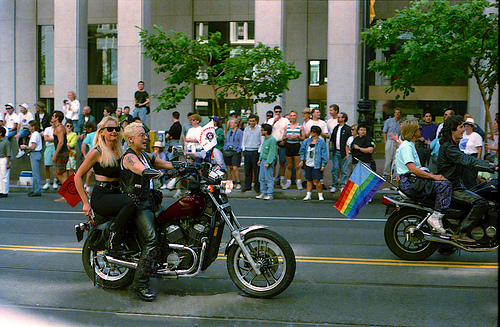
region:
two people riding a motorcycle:
[71, 116, 298, 308]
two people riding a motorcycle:
[369, 116, 499, 261]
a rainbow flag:
[326, 151, 400, 226]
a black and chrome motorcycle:
[71, 159, 297, 297]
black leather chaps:
[126, 192, 165, 291]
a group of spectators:
[213, 103, 346, 205]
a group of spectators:
[0, 96, 80, 194]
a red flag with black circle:
[51, 166, 87, 213]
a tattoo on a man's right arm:
[121, 150, 139, 170]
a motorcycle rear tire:
[379, 202, 437, 264]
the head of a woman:
[92, 115, 122, 145]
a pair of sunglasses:
[101, 124, 122, 134]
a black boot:
[128, 247, 158, 304]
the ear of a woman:
[97, 126, 105, 137]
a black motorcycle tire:
[224, 225, 297, 299]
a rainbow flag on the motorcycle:
[327, 155, 385, 221]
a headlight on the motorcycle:
[218, 177, 238, 195]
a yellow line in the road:
[1, 239, 498, 275]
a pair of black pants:
[88, 182, 138, 234]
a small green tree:
[126, 15, 303, 112]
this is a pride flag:
[321, 137, 404, 229]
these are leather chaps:
[130, 187, 169, 325]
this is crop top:
[93, 145, 123, 176]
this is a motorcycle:
[49, 167, 321, 314]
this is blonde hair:
[84, 112, 141, 183]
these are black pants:
[84, 167, 149, 268]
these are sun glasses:
[92, 122, 126, 135]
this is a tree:
[132, 23, 312, 155]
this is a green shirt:
[251, 129, 281, 171]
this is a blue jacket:
[298, 131, 340, 165]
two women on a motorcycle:
[68, 110, 300, 317]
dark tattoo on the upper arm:
[123, 153, 139, 170]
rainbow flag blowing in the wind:
[331, 152, 381, 227]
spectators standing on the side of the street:
[6, 89, 494, 201]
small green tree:
[140, 23, 291, 141]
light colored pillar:
[323, 0, 363, 140]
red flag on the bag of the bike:
[53, 173, 105, 240]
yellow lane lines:
[2, 231, 497, 275]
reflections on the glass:
[89, 26, 119, 85]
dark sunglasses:
[105, 122, 122, 132]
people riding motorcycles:
[73, 106, 498, 306]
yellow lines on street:
[1, 237, 496, 277]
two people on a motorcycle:
[72, 108, 233, 303]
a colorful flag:
[331, 150, 397, 230]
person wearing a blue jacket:
[291, 125, 331, 171]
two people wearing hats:
[1, 97, 31, 117]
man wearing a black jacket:
[327, 107, 352, 154]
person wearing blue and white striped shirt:
[280, 110, 305, 145]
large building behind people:
[1, 0, 496, 171]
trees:
[131, 0, 498, 138]